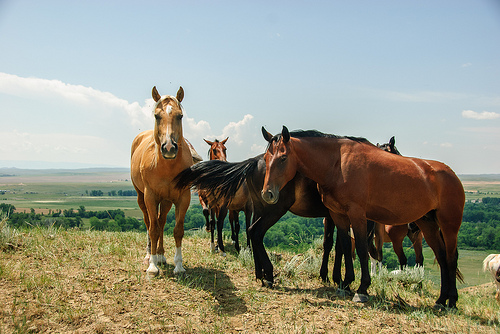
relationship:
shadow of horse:
[156, 255, 250, 317] [125, 87, 199, 279]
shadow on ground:
[156, 255, 250, 317] [1, 215, 498, 332]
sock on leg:
[169, 247, 185, 273] [174, 199, 188, 277]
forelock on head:
[156, 94, 179, 109] [144, 85, 194, 160]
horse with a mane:
[256, 122, 464, 307] [291, 129, 371, 149]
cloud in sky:
[458, 105, 498, 122] [18, 9, 483, 184]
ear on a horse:
[279, 126, 294, 145] [125, 87, 199, 279]